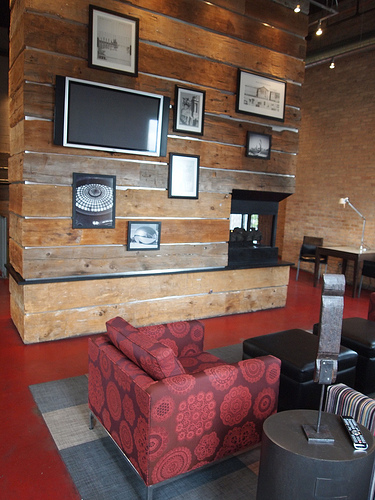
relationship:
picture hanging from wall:
[230, 65, 296, 127] [6, 2, 312, 282]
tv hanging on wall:
[47, 68, 176, 165] [6, 2, 312, 282]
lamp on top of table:
[296, 270, 352, 450] [250, 406, 374, 499]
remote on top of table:
[337, 410, 370, 455] [250, 406, 374, 499]